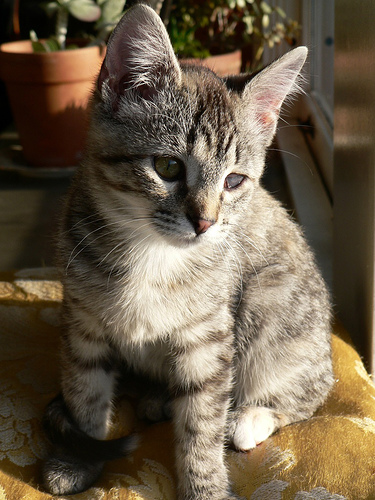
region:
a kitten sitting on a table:
[43, 7, 325, 498]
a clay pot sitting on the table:
[1, 36, 111, 161]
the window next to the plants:
[269, 2, 342, 187]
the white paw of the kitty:
[220, 399, 275, 456]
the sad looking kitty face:
[126, 129, 252, 244]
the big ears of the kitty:
[106, 2, 308, 105]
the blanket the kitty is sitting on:
[0, 274, 369, 495]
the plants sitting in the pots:
[30, 0, 281, 58]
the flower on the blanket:
[3, 371, 50, 464]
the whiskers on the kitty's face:
[64, 205, 281, 306]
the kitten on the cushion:
[35, 2, 337, 498]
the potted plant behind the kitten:
[0, 33, 98, 162]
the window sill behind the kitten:
[279, 125, 344, 259]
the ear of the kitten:
[100, 3, 188, 96]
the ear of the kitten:
[204, 45, 313, 126]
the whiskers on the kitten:
[90, 197, 156, 261]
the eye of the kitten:
[126, 143, 181, 179]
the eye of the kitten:
[224, 168, 247, 194]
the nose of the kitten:
[185, 204, 216, 238]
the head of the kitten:
[73, 3, 307, 255]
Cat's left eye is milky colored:
[222, 172, 246, 191]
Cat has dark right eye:
[155, 155, 181, 184]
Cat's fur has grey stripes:
[173, 332, 228, 348]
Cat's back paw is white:
[233, 400, 276, 451]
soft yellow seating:
[267, 429, 370, 496]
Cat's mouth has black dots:
[150, 212, 175, 233]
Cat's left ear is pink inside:
[249, 79, 282, 118]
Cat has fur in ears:
[120, 35, 157, 87]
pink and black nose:
[190, 217, 213, 235]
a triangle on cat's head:
[220, 127, 241, 163]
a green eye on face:
[141, 141, 201, 198]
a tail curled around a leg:
[49, 401, 145, 462]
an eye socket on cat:
[224, 164, 248, 192]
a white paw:
[231, 409, 300, 451]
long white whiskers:
[99, 206, 162, 268]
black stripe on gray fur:
[177, 337, 221, 488]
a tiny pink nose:
[197, 215, 208, 232]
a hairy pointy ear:
[98, 13, 177, 87]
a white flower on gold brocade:
[0, 400, 42, 466]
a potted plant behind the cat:
[5, 34, 95, 166]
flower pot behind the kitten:
[9, 31, 101, 163]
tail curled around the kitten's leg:
[27, 392, 143, 469]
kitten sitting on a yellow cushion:
[19, 92, 277, 485]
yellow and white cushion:
[302, 426, 362, 497]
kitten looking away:
[68, 7, 316, 265]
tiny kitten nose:
[188, 205, 214, 239]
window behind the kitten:
[294, 0, 341, 180]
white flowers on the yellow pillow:
[3, 352, 45, 473]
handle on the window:
[294, 112, 317, 145]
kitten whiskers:
[81, 212, 193, 244]